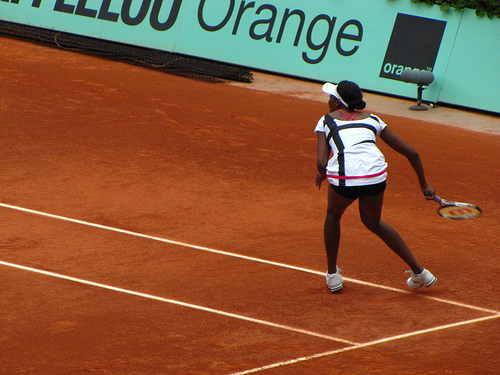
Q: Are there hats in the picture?
A: Yes, there is a hat.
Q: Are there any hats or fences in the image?
A: Yes, there is a hat.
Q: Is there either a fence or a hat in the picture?
A: Yes, there is a hat.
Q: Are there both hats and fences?
A: No, there is a hat but no fences.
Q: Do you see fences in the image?
A: No, there are no fences.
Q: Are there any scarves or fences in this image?
A: No, there are no fences or scarves.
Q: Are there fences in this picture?
A: No, there are no fences.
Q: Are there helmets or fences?
A: No, there are no fences or helmets.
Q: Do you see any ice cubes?
A: No, there are no ice cubes.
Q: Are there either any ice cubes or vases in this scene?
A: No, there are no ice cubes or vases.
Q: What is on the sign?
A: The letter is on the sign.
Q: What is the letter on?
A: The letter is on the sign.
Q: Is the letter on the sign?
A: Yes, the letter is on the sign.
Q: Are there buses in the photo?
A: No, there are no buses.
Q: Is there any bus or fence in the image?
A: No, there are no buses or fences.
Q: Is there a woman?
A: Yes, there is a woman.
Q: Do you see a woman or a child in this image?
A: Yes, there is a woman.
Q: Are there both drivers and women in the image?
A: No, there is a woman but no drivers.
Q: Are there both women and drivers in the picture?
A: No, there is a woman but no drivers.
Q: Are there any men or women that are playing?
A: Yes, the woman is playing.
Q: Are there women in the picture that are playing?
A: Yes, there is a woman that is playing.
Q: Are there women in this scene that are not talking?
A: Yes, there is a woman that is playing.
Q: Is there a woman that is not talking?
A: Yes, there is a woman that is playing.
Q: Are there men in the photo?
A: No, there are no men.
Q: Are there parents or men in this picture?
A: No, there are no men or parents.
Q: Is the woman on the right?
A: Yes, the woman is on the right of the image.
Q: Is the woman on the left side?
A: No, the woman is on the right of the image.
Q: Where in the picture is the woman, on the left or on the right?
A: The woman is on the right of the image.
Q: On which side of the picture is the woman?
A: The woman is on the right of the image.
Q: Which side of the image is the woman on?
A: The woman is on the right of the image.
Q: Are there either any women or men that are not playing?
A: No, there is a woman but she is playing.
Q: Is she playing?
A: Yes, the woman is playing.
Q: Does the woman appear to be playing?
A: Yes, the woman is playing.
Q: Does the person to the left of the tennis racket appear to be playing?
A: Yes, the woman is playing.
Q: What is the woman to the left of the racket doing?
A: The woman is playing.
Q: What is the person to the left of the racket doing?
A: The woman is playing.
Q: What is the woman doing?
A: The woman is playing.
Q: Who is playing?
A: The woman is playing.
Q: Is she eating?
A: No, the woman is playing.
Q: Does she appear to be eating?
A: No, the woman is playing.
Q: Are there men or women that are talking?
A: No, there is a woman but she is playing.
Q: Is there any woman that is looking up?
A: No, there is a woman but she is playing.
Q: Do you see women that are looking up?
A: No, there is a woman but she is playing.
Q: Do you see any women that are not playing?
A: No, there is a woman but she is playing.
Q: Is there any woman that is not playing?
A: No, there is a woman but she is playing.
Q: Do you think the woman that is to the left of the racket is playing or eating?
A: The woman is playing.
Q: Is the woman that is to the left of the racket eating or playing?
A: The woman is playing.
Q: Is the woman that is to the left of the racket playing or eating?
A: The woman is playing.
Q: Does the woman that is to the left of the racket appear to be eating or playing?
A: The woman is playing.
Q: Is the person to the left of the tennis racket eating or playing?
A: The woman is playing.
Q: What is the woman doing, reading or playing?
A: The woman is playing.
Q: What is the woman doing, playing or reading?
A: The woman is playing.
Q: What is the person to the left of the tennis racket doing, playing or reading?
A: The woman is playing.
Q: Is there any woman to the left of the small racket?
A: Yes, there is a woman to the left of the racket.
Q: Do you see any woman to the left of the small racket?
A: Yes, there is a woman to the left of the racket.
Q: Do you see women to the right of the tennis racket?
A: No, the woman is to the left of the tennis racket.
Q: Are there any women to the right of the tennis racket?
A: No, the woman is to the left of the tennis racket.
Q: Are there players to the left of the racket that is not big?
A: No, there is a woman to the left of the racket.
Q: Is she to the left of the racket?
A: Yes, the woman is to the left of the racket.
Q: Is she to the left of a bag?
A: No, the woman is to the left of the racket.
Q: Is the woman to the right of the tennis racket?
A: No, the woman is to the left of the tennis racket.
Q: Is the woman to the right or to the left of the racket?
A: The woman is to the left of the racket.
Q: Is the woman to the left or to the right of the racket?
A: The woman is to the left of the racket.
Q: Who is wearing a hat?
A: The woman is wearing a hat.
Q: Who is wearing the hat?
A: The woman is wearing a hat.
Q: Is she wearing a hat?
A: Yes, the woman is wearing a hat.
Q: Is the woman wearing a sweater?
A: No, the woman is wearing a hat.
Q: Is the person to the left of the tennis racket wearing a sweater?
A: No, the woman is wearing a hat.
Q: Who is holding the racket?
A: The woman is holding the racket.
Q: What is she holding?
A: The woman is holding the racket.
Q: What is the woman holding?
A: The woman is holding the racket.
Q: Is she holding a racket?
A: Yes, the woman is holding a racket.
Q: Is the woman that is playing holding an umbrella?
A: No, the woman is holding a racket.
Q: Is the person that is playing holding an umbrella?
A: No, the woman is holding a racket.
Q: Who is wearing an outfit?
A: The woman is wearing an outfit.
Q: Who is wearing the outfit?
A: The woman is wearing an outfit.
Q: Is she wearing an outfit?
A: Yes, the woman is wearing an outfit.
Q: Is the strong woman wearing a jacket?
A: No, the woman is wearing an outfit.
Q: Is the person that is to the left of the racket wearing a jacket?
A: No, the woman is wearing an outfit.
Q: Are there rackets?
A: Yes, there is a racket.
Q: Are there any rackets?
A: Yes, there is a racket.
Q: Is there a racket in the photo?
A: Yes, there is a racket.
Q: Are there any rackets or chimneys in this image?
A: Yes, there is a racket.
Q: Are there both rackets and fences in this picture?
A: No, there is a racket but no fences.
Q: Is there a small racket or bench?
A: Yes, there is a small racket.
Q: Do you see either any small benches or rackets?
A: Yes, there is a small racket.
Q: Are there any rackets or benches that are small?
A: Yes, the racket is small.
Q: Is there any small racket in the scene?
A: Yes, there is a small racket.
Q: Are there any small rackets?
A: Yes, there is a small racket.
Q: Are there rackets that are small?
A: Yes, there is a racket that is small.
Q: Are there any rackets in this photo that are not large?
A: Yes, there is a small racket.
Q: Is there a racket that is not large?
A: Yes, there is a small racket.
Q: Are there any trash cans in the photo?
A: No, there are no trash cans.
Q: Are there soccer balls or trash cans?
A: No, there are no trash cans or soccer balls.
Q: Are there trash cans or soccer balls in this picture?
A: No, there are no trash cans or soccer balls.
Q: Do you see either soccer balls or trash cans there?
A: No, there are no trash cans or soccer balls.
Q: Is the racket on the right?
A: Yes, the racket is on the right of the image.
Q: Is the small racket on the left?
A: No, the racket is on the right of the image.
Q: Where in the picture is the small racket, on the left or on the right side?
A: The tennis racket is on the right of the image.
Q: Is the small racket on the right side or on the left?
A: The tennis racket is on the right of the image.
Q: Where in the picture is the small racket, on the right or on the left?
A: The tennis racket is on the right of the image.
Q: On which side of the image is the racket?
A: The racket is on the right of the image.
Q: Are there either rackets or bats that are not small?
A: No, there is a racket but it is small.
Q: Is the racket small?
A: Yes, the racket is small.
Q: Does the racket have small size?
A: Yes, the racket is small.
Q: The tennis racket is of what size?
A: The tennis racket is small.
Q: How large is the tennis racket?
A: The tennis racket is small.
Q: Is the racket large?
A: No, the racket is small.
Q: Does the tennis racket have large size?
A: No, the tennis racket is small.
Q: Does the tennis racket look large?
A: No, the tennis racket is small.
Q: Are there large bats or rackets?
A: No, there is a racket but it is small.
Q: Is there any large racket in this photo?
A: No, there is a racket but it is small.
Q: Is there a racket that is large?
A: No, there is a racket but it is small.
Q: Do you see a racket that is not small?
A: No, there is a racket but it is small.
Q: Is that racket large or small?
A: The racket is small.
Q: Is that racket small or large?
A: The racket is small.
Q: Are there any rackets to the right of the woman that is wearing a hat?
A: Yes, there is a racket to the right of the woman.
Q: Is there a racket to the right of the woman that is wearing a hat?
A: Yes, there is a racket to the right of the woman.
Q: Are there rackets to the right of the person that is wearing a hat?
A: Yes, there is a racket to the right of the woman.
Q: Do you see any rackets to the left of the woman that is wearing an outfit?
A: No, the racket is to the right of the woman.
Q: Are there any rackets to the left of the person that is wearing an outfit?
A: No, the racket is to the right of the woman.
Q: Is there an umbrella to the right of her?
A: No, there is a racket to the right of the woman.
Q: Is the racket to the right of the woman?
A: Yes, the racket is to the right of the woman.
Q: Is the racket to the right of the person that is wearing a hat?
A: Yes, the racket is to the right of the woman.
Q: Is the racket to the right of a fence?
A: No, the racket is to the right of the woman.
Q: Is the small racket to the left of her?
A: No, the racket is to the right of a woman.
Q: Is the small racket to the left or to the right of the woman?
A: The racket is to the right of the woman.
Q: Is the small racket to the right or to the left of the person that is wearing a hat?
A: The racket is to the right of the woman.